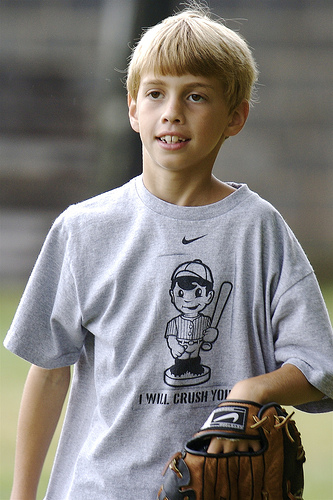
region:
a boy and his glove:
[115, 76, 310, 347]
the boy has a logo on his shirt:
[102, 255, 249, 406]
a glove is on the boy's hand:
[151, 385, 300, 498]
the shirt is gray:
[53, 183, 306, 342]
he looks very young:
[114, 23, 267, 184]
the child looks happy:
[95, 21, 270, 237]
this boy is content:
[120, 13, 254, 180]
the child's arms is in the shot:
[5, 346, 322, 495]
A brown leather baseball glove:
[155, 398, 309, 498]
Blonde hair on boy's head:
[124, 9, 259, 172]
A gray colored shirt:
[2, 173, 331, 497]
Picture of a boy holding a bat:
[160, 255, 236, 386]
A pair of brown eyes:
[143, 85, 209, 107]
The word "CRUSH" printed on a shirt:
[170, 386, 209, 406]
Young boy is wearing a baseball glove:
[4, 5, 331, 497]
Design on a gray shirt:
[130, 228, 241, 408]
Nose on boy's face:
[160, 95, 188, 129]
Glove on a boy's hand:
[158, 378, 310, 498]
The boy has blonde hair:
[121, 13, 259, 176]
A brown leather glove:
[146, 392, 311, 497]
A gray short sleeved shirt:
[3, 171, 331, 497]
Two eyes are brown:
[141, 83, 210, 110]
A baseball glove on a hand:
[152, 378, 308, 498]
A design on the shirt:
[134, 229, 241, 408]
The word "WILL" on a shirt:
[142, 388, 171, 408]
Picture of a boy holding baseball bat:
[162, 254, 236, 373]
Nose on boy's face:
[158, 101, 187, 129]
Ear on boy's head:
[220, 98, 254, 142]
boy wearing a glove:
[2, 2, 328, 497]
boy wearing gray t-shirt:
[2, 1, 330, 490]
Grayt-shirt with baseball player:
[1, 169, 331, 499]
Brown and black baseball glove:
[145, 396, 331, 496]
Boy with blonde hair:
[1, 2, 331, 498]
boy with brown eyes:
[120, 6, 268, 177]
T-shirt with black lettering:
[1, 169, 331, 499]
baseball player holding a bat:
[161, 254, 235, 387]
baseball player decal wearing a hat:
[157, 252, 236, 391]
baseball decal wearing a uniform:
[157, 255, 237, 390]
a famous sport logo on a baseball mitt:
[213, 409, 245, 426]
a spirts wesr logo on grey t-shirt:
[180, 229, 208, 244]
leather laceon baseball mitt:
[249, 410, 294, 441]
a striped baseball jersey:
[164, 315, 210, 336]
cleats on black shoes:
[170, 358, 206, 377]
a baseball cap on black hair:
[169, 256, 211, 290]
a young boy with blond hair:
[125, 5, 257, 184]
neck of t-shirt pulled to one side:
[128, 173, 250, 216]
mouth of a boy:
[156, 129, 190, 150]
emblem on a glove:
[207, 406, 254, 434]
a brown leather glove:
[165, 394, 311, 499]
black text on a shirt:
[133, 388, 229, 410]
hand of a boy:
[200, 404, 263, 457]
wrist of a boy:
[234, 383, 266, 402]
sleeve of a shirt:
[0, 268, 68, 373]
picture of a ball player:
[157, 263, 239, 394]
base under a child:
[163, 373, 213, 392]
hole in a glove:
[183, 432, 269, 461]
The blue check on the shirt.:
[179, 235, 212, 252]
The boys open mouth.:
[154, 131, 194, 149]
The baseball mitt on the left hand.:
[159, 392, 319, 499]